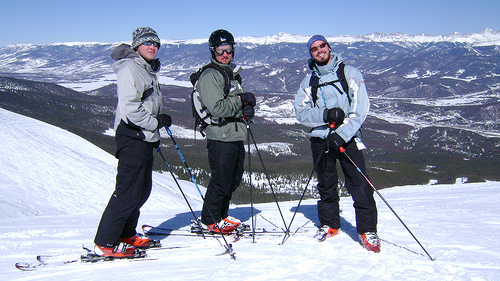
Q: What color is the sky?
A: Blue.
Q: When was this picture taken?
A: Day time.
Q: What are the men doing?
A: Skiing.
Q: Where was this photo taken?
A: On a mountain.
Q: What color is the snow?
A: White.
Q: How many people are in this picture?
A: Three.